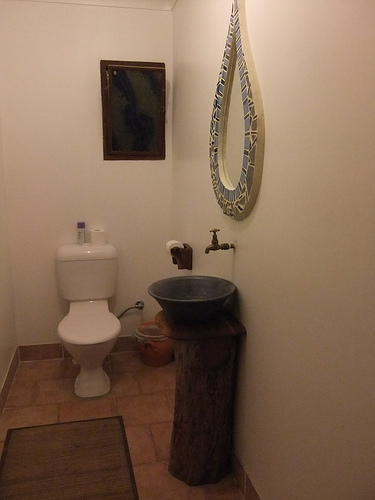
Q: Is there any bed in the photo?
A: No, there are no beds.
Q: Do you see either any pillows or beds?
A: No, there are no beds or pillows.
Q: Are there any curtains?
A: No, there are no curtains.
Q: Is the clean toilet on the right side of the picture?
A: No, the toilet is on the left of the image.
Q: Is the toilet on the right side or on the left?
A: The toilet is on the left of the image.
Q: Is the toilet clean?
A: Yes, the toilet is clean.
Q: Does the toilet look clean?
A: Yes, the toilet is clean.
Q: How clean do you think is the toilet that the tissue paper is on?
A: The toilet is clean.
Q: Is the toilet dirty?
A: No, the toilet is clean.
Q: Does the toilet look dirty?
A: No, the toilet is clean.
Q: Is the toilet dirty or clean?
A: The toilet is clean.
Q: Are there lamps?
A: No, there are no lamps.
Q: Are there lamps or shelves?
A: No, there are no lamps or shelves.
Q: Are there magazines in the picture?
A: No, there are no magazines.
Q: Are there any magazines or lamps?
A: No, there are no magazines or lamps.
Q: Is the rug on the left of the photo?
A: Yes, the rug is on the left of the image.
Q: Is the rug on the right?
A: No, the rug is on the left of the image.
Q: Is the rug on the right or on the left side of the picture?
A: The rug is on the left of the image.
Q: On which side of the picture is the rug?
A: The rug is on the left of the image.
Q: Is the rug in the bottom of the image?
A: Yes, the rug is in the bottom of the image.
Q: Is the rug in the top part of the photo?
A: No, the rug is in the bottom of the image.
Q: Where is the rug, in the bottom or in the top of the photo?
A: The rug is in the bottom of the image.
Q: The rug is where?
A: The rug is on the floor.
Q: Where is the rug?
A: The rug is on the floor.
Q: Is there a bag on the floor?
A: No, there is a rug on the floor.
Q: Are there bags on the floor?
A: No, there is a rug on the floor.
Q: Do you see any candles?
A: No, there are no candles.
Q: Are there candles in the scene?
A: No, there are no candles.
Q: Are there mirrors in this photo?
A: Yes, there is a mirror.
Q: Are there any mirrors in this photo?
A: Yes, there is a mirror.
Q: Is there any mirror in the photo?
A: Yes, there is a mirror.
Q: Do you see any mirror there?
A: Yes, there is a mirror.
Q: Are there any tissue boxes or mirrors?
A: Yes, there is a mirror.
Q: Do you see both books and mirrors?
A: No, there is a mirror but no books.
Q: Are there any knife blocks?
A: No, there are no knife blocks.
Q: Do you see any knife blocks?
A: No, there are no knife blocks.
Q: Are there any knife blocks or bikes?
A: No, there are no knife blocks or bikes.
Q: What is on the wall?
A: The mirror is on the wall.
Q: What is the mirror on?
A: The mirror is on the wall.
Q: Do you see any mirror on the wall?
A: Yes, there is a mirror on the wall.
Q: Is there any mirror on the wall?
A: Yes, there is a mirror on the wall.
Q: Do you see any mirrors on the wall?
A: Yes, there is a mirror on the wall.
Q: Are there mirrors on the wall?
A: Yes, there is a mirror on the wall.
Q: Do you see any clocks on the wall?
A: No, there is a mirror on the wall.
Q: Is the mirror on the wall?
A: Yes, the mirror is on the wall.